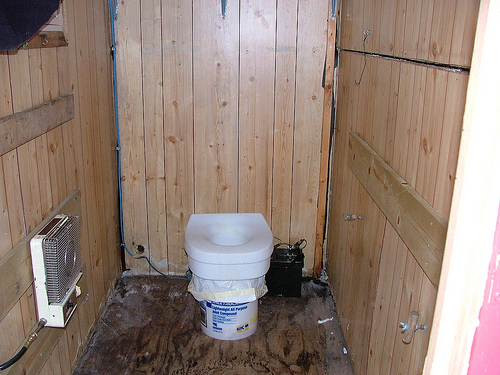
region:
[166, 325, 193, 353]
part of a floor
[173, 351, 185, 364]
part of a floor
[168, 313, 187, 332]
part of a floor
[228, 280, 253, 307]
part of a paper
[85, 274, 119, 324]
[art of a wall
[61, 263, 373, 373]
THE FLOOR IS PLYWOOD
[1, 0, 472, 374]
THE OUTHOUSE IS WOODEN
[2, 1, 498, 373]
THE WALLS ARE WOOD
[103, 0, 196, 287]
THE CORD IS BLUE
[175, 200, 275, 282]
THE SEAT IS WHITE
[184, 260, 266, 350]
THE BUCKET IS WHITE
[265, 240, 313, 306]
THE BATTERY IS BLACK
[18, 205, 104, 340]
THE HEATER IS ON THE WALL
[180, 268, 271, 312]
THE BAG IS IN THE BUCKET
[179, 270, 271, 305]
THE BAG IS WHITE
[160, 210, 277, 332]
A toilet sitting on a bucket.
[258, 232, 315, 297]
A black bucket by the wall.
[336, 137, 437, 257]
A wooden panel across the wall.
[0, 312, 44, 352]
A pipe on the side of the wall.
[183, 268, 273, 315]
A plastic bag in the bucket.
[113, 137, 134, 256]
A wire running down the corner of the wall.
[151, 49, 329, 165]
The wall is made of wood.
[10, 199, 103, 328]
An a/c unit on the side of the wall.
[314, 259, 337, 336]
The floor is molded and dirty.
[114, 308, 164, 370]
Stains on the floor.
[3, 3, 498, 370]
an outhouse on an island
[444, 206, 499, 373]
the outhouse is pink on the outside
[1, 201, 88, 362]
a fan heater is in the room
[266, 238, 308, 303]
a trash can is in the room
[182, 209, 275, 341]
a plastic toilet seat is on top of a bucket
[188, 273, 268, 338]
the bucket has a plastic bag is under the toilet seat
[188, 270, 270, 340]
the plastic bag is on a bucket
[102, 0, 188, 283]
a wire is running along the corner of the room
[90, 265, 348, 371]
the floor in the outhouse is plywood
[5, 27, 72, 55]
hooks are on the wall of the room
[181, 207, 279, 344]
questionable portable toilet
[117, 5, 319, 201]
cheap wood paneling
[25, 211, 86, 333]
white and silver wall heater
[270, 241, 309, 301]
black car battery near toilet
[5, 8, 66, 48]
wooden bottom of a window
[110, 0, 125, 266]
blue electrical cord running down wall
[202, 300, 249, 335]
blue print on white bucket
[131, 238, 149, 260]
small hole drilled in paneling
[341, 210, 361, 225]
screw sticking out of wall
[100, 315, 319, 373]
water damaged wooden subfloor